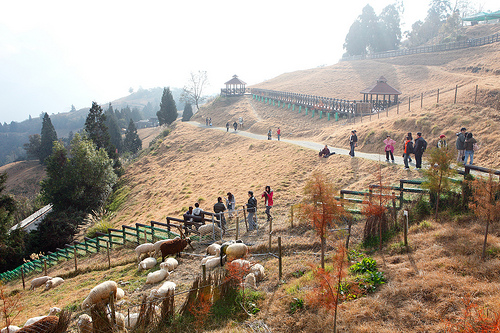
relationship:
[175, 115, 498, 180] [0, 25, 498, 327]
sidewalk on hillside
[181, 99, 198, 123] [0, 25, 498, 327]
tree on hillside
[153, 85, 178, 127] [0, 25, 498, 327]
tree on hillside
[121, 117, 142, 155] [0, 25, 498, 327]
tree on hillside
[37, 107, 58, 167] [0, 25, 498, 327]
tree on hillside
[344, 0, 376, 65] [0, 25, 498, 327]
tree on hillside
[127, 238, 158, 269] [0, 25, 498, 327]
sheep on hillside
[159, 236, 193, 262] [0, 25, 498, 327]
sheep on hillside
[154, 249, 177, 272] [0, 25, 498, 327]
sheep on hillside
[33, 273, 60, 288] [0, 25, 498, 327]
sheep on hillside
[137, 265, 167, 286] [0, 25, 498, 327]
sheep on hillside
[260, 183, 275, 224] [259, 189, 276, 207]
girl wearing jacket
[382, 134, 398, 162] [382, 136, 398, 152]
people wearing jacket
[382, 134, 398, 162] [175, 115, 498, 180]
people on sidewalk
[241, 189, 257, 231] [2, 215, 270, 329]
man looking at animals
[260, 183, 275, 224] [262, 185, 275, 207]
girl wearing jacket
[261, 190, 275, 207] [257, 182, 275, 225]
shirt on woman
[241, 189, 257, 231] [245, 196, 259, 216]
man wearing jacket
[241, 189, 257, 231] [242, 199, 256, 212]
man wearing jacket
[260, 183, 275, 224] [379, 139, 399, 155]
girl wearing shirt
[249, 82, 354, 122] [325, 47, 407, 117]
walkway by gazebos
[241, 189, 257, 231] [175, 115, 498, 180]
man on sidewalk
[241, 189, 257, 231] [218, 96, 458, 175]
man on road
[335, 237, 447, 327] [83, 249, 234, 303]
grass by sheep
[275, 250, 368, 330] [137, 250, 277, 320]
trees by sheep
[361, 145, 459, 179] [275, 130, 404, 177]
people on sidewalk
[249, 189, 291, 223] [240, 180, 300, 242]
shirt on person